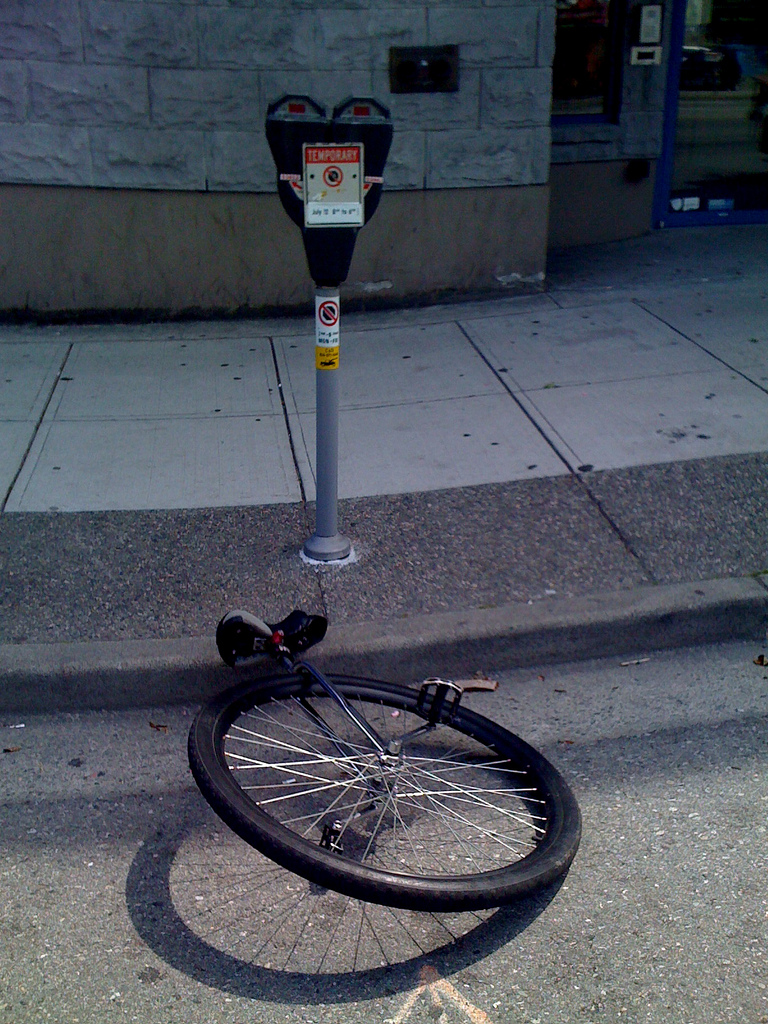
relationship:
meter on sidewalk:
[265, 92, 396, 290] [72, 375, 595, 640]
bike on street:
[184, 605, 587, 914] [58, 579, 641, 972]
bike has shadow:
[184, 605, 587, 914] [118, 875, 355, 1014]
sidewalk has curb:
[17, 310, 766, 675] [2, 585, 767, 703]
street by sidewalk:
[2, 691, 767, 1021] [17, 310, 766, 675]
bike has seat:
[184, 605, 587, 914] [204, 596, 336, 665]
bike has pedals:
[184, 605, 587, 914] [299, 666, 511, 854]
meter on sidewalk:
[265, 92, 396, 290] [17, 310, 766, 675]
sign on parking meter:
[299, 139, 366, 228] [255, 86, 404, 274]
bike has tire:
[184, 605, 587, 914] [171, 650, 589, 918]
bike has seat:
[171, 589, 602, 910] [199, 596, 352, 665]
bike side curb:
[184, 605, 587, 914] [3, 581, 762, 695]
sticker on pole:
[306, 294, 350, 373] [303, 294, 354, 562]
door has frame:
[653, 5, 767, 240] [653, 1, 764, 234]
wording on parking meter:
[303, 149, 361, 167] [248, 81, 411, 290]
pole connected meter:
[295, 289, 355, 564] [252, 83, 391, 293]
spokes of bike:
[338, 786, 469, 871] [184, 605, 587, 914]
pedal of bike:
[393, 663, 482, 745] [184, 605, 587, 914]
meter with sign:
[253, 80, 401, 565] [302, 136, 367, 230]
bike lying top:
[184, 605, 587, 914] [627, 885, 699, 995]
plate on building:
[383, 41, 472, 106] [7, 11, 579, 312]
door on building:
[648, 0, 768, 233] [648, 29, 719, 251]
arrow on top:
[365, 953, 517, 1024] [622, 867, 718, 1013]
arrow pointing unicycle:
[365, 953, 517, 1021] [177, 600, 625, 936]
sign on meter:
[301, 142, 365, 228] [235, 86, 408, 292]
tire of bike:
[199, 667, 587, 896] [184, 605, 587, 914]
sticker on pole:
[316, 296, 340, 371] [302, 287, 353, 564]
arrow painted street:
[365, 953, 517, 1024] [2, 636, 768, 1021]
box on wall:
[375, 34, 481, 89] [3, 2, 546, 292]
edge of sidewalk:
[482, 632, 610, 654] [13, 303, 704, 608]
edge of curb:
[482, 632, 610, 654] [548, 615, 694, 708]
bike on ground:
[184, 605, 587, 914] [593, 754, 729, 907]